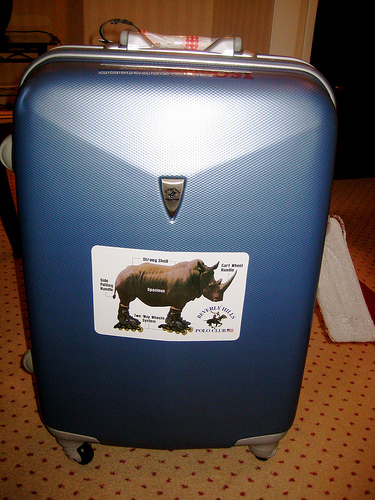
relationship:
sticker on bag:
[89, 240, 254, 342] [12, 44, 336, 466]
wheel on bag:
[59, 435, 98, 467] [12, 44, 336, 466]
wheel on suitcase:
[248, 439, 277, 467] [18, 30, 318, 469]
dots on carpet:
[163, 461, 233, 498] [312, 347, 369, 498]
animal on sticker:
[113, 258, 237, 329] [89, 240, 254, 342]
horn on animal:
[220, 266, 241, 299] [113, 258, 237, 329]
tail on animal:
[106, 276, 119, 307] [113, 258, 237, 329]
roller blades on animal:
[158, 307, 194, 336] [113, 258, 237, 329]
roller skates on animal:
[113, 304, 143, 333] [113, 258, 237, 329]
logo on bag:
[154, 172, 191, 224] [12, 44, 336, 466]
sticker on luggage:
[89, 240, 254, 342] [19, 53, 341, 466]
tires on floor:
[53, 435, 283, 465] [113, 466, 250, 491]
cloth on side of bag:
[318, 215, 373, 348] [12, 44, 336, 466]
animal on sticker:
[113, 257, 235, 334] [89, 240, 254, 342]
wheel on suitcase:
[73, 441, 95, 465] [23, 57, 310, 453]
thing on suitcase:
[145, 169, 211, 233] [23, 57, 310, 453]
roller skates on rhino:
[113, 304, 143, 333] [93, 257, 241, 347]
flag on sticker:
[209, 324, 245, 338] [91, 244, 250, 342]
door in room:
[322, 15, 373, 129] [13, 8, 360, 485]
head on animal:
[190, 261, 236, 302] [113, 258, 237, 329]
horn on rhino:
[220, 270, 237, 294] [97, 248, 225, 333]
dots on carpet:
[275, 435, 324, 473] [262, 407, 369, 496]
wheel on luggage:
[73, 441, 95, 465] [23, 61, 325, 414]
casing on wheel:
[54, 432, 85, 460] [85, 439, 112, 468]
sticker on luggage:
[91, 244, 250, 342] [28, 69, 334, 473]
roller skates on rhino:
[103, 304, 220, 342] [101, 256, 285, 334]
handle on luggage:
[118, 28, 242, 53] [46, 57, 301, 442]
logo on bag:
[159, 174, 187, 223] [40, 67, 282, 498]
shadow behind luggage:
[1, 240, 37, 312] [19, 53, 341, 466]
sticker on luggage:
[91, 244, 250, 342] [34, 53, 312, 468]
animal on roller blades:
[113, 258, 237, 329] [107, 308, 194, 337]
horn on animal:
[220, 270, 237, 294] [113, 258, 237, 329]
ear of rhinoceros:
[195, 261, 205, 273] [109, 259, 237, 329]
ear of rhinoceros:
[210, 259, 220, 271] [109, 259, 237, 329]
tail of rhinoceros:
[112, 283, 117, 299] [109, 259, 237, 329]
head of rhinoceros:
[197, 267, 223, 302] [109, 259, 237, 329]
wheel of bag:
[73, 441, 95, 465] [12, 44, 336, 466]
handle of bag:
[118, 28, 242, 53] [12, 44, 336, 466]